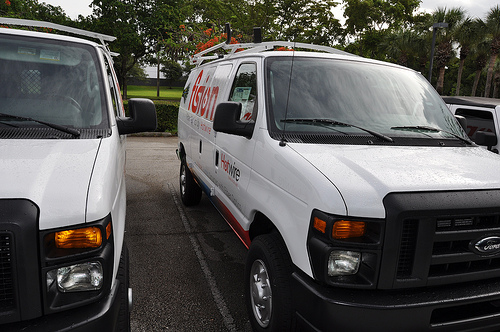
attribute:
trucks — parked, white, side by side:
[2, 47, 445, 290]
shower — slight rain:
[421, 4, 489, 29]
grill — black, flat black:
[397, 202, 488, 255]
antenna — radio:
[277, 31, 297, 136]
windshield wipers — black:
[283, 109, 436, 143]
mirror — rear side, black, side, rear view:
[209, 105, 263, 138]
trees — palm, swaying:
[394, 6, 500, 71]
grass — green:
[122, 77, 191, 100]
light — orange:
[335, 216, 380, 242]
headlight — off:
[324, 247, 363, 277]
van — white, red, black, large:
[172, 52, 465, 272]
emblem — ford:
[474, 234, 500, 247]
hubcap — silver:
[243, 262, 271, 323]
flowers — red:
[196, 20, 237, 50]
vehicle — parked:
[185, 49, 457, 259]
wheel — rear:
[174, 164, 211, 213]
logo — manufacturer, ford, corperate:
[476, 233, 499, 251]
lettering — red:
[189, 66, 229, 131]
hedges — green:
[124, 101, 185, 129]